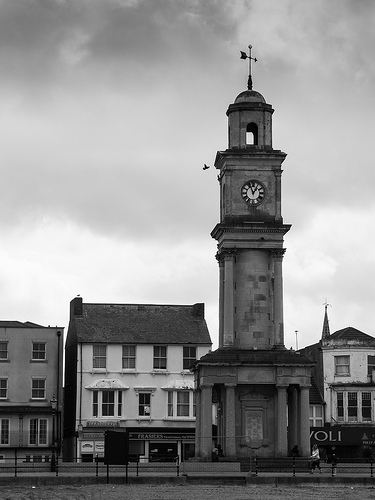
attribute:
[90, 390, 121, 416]
window — large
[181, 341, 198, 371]
window — large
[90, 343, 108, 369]
window — large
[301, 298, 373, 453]
building — white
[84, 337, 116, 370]
window — large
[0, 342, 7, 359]
window — large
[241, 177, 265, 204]
clockface — white, round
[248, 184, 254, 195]
hands — black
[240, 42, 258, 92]
vane — large, metal, weather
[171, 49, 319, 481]
tower — tall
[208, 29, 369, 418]
tower — round, white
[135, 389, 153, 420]
window — large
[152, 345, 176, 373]
window — large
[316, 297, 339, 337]
decoration — christmas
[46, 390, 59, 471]
lamp post — black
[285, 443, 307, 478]
post — black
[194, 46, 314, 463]
tower — clock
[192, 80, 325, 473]
tower — clock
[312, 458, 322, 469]
pants — black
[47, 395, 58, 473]
lamp post — black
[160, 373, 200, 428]
window — large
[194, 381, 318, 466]
pillars — gray